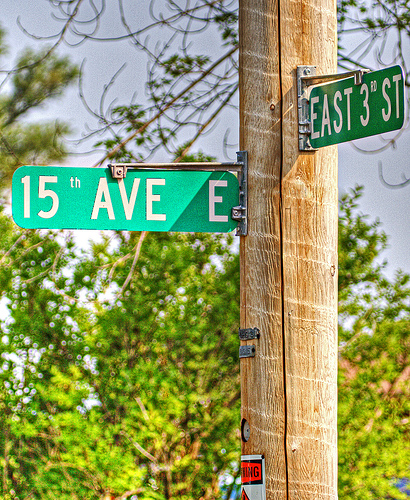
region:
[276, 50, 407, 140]
a small display for board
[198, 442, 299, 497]
a part of the text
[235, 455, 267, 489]
red board with black text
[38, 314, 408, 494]
cool green color trees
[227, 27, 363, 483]
a long pillar on road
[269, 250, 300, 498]
a small line in pillar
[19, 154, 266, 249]
a green board with white text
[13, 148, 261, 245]
a green board with address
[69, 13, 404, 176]
clear view of sky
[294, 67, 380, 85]
a small hanger holding board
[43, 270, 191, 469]
bright green trees outside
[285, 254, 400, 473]
brown post and trees outside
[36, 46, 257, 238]
street sign and barren tree branches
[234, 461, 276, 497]
warning label on brown post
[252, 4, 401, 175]
green street sign hanging on brown post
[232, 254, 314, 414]
brown post split and metal brackets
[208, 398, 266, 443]
green leaves and hole in post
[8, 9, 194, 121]
bare tree branches hanging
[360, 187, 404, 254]
grey sky and green leaves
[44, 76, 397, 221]
pair of signs hanging on a post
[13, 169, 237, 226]
15th Ave E on a sign.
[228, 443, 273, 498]
Warning sign on a pole.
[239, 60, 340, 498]
The pole is wooden.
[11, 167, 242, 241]
The background of the sign is green.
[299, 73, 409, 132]
East 3rd St on a sign.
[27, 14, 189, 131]
The sky is blue.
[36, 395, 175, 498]
The tree is green.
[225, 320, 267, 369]
Tags on the pole.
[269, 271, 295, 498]
Crack in the pole.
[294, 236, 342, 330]
Scratches on the pole.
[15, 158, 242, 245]
The sign says "15th AVE E"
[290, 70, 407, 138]
The right sign says "East 3rd St"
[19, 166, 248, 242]
A green sign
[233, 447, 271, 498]
A partially visible warning sign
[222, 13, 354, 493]
A large wooden pole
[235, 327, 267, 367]
Dull metal clasps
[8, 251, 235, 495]
Green trees behind the pole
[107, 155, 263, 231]
A metal sign holder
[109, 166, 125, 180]
A small screw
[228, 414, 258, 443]
A large metal screw in the pole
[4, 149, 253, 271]
15th Ave East street sign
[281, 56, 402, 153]
east 3rd street sign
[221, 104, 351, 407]
A wooden sign pole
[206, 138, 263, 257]
metallic sign attachment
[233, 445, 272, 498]
A warning sign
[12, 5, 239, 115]
The sky behind some trees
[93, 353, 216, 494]
A couple of blurred trees.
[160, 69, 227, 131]
A couple of blurred branches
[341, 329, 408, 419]
A building in the background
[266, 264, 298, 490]
A crack in the wooden pole